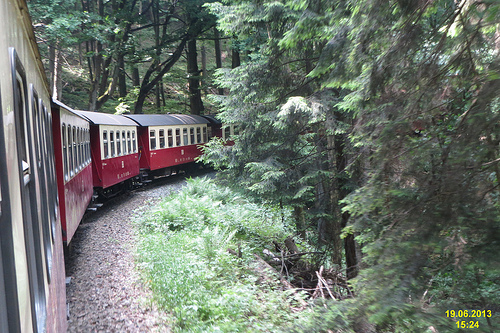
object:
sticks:
[314, 271, 337, 303]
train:
[0, 0, 241, 333]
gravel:
[111, 226, 118, 232]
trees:
[335, 0, 499, 333]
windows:
[196, 126, 203, 143]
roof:
[124, 113, 211, 126]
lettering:
[443, 307, 493, 329]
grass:
[133, 176, 355, 332]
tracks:
[98, 169, 205, 200]